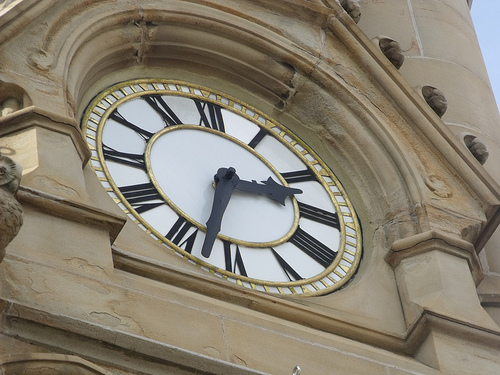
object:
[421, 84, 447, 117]
knob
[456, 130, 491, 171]
ground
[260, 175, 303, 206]
arrow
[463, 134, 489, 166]
knob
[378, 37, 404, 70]
knob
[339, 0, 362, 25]
knob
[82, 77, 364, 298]
filagree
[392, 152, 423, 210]
ground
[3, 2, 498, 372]
wall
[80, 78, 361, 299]
clock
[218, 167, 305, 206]
hand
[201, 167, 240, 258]
hand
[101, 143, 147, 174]
numeral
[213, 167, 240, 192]
pin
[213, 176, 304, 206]
arm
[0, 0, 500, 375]
building surface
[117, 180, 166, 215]
number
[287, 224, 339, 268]
number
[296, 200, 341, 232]
number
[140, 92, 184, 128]
number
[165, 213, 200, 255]
number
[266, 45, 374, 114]
sculptures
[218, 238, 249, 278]
number